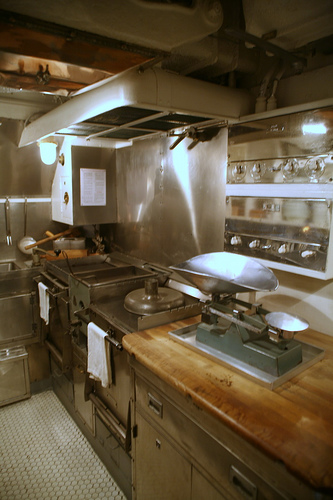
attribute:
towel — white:
[83, 319, 107, 389]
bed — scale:
[178, 249, 279, 299]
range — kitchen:
[53, 63, 220, 143]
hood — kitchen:
[58, 63, 227, 147]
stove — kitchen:
[40, 260, 82, 376]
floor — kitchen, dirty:
[43, 436, 89, 484]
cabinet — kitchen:
[127, 422, 205, 483]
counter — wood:
[159, 347, 301, 446]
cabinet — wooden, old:
[128, 359, 279, 490]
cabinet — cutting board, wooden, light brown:
[116, 346, 316, 487]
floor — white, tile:
[43, 447, 88, 476]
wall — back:
[0, 186, 44, 208]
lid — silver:
[132, 273, 169, 303]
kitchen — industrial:
[12, 27, 320, 460]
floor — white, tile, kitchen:
[26, 438, 79, 481]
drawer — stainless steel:
[133, 370, 291, 498]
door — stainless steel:
[131, 407, 191, 498]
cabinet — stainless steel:
[128, 358, 332, 498]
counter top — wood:
[121, 306, 332, 499]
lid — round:
[122, 278, 186, 316]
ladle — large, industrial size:
[17, 194, 36, 253]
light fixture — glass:
[35, 137, 60, 164]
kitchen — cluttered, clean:
[0, 1, 332, 498]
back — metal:
[118, 126, 228, 284]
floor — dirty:
[0, 390, 128, 498]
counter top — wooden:
[116, 289, 330, 490]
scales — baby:
[158, 236, 326, 401]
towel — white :
[74, 314, 127, 407]